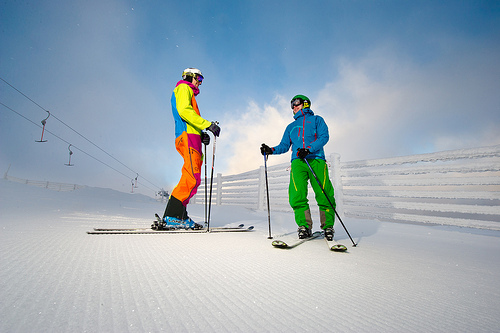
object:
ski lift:
[0, 76, 175, 211]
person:
[152, 64, 221, 229]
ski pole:
[195, 126, 213, 233]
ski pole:
[207, 130, 220, 235]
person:
[258, 94, 335, 242]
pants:
[288, 157, 336, 228]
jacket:
[266, 108, 329, 161]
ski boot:
[159, 213, 200, 229]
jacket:
[169, 81, 210, 134]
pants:
[163, 132, 205, 229]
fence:
[188, 144, 500, 232]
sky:
[2, 1, 499, 183]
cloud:
[209, 39, 499, 163]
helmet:
[289, 94, 312, 108]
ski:
[84, 227, 254, 234]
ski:
[93, 222, 249, 231]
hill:
[1, 179, 162, 207]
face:
[193, 72, 203, 90]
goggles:
[182, 71, 203, 83]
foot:
[162, 216, 195, 226]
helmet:
[181, 68, 203, 81]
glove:
[207, 121, 221, 136]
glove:
[197, 132, 209, 146]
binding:
[297, 224, 310, 240]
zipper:
[299, 106, 308, 158]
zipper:
[288, 168, 300, 195]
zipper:
[321, 160, 328, 194]